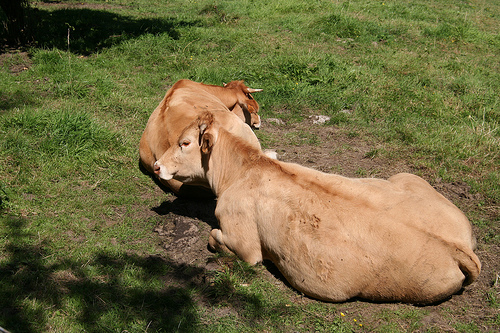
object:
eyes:
[179, 142, 194, 147]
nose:
[156, 145, 174, 164]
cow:
[152, 109, 482, 308]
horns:
[243, 88, 265, 95]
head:
[153, 111, 225, 181]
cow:
[140, 78, 261, 206]